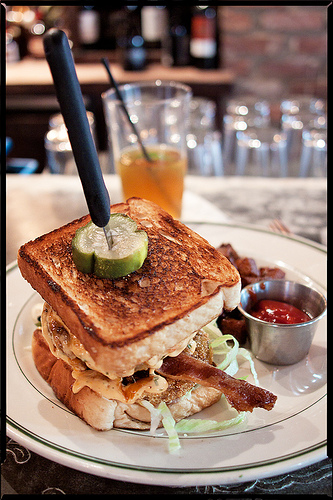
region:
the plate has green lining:
[218, 465, 223, 471]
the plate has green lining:
[249, 458, 258, 476]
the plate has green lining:
[152, 466, 155, 470]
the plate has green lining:
[249, 462, 254, 470]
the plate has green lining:
[237, 464, 245, 470]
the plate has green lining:
[246, 459, 252, 473]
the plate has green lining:
[214, 465, 216, 469]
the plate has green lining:
[275, 456, 283, 465]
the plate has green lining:
[156, 465, 158, 470]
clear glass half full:
[100, 80, 187, 212]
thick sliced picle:
[76, 212, 148, 272]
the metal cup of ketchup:
[239, 276, 323, 359]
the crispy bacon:
[164, 352, 279, 414]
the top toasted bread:
[24, 199, 241, 338]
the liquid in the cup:
[120, 154, 184, 221]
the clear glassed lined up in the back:
[188, 92, 323, 165]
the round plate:
[8, 217, 331, 480]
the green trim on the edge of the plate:
[4, 447, 328, 497]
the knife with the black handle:
[46, 67, 116, 252]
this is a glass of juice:
[119, 91, 190, 191]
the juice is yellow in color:
[138, 168, 179, 190]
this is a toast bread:
[157, 240, 203, 305]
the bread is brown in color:
[158, 244, 201, 296]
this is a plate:
[252, 419, 298, 448]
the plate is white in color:
[240, 423, 280, 460]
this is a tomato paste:
[264, 303, 293, 323]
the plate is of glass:
[248, 413, 317, 449]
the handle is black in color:
[74, 139, 104, 192]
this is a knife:
[102, 221, 115, 236]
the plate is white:
[130, 427, 245, 465]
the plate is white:
[159, 423, 222, 458]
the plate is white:
[169, 428, 250, 480]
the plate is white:
[189, 459, 266, 488]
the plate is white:
[181, 411, 253, 456]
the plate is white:
[185, 403, 224, 447]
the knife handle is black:
[8, 35, 139, 248]